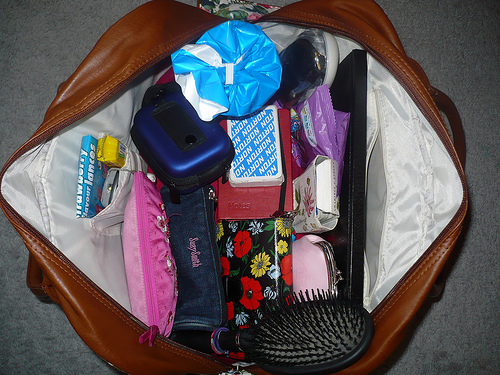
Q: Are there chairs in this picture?
A: No, there are no chairs.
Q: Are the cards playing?
A: Yes, the cards are playing.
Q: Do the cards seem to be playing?
A: Yes, the cards are playing.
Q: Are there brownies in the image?
A: No, there are no brownies.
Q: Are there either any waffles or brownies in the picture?
A: No, there are no brownies or waffles.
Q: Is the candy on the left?
A: Yes, the candy is on the left of the image.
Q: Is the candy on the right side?
A: No, the candy is on the left of the image.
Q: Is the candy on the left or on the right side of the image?
A: The candy is on the left of the image.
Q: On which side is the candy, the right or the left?
A: The candy is on the left of the image.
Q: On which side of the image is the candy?
A: The candy is on the left of the image.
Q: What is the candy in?
A: The candy is in the bag.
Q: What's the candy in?
A: The candy is in the bag.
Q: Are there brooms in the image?
A: No, there are no brooms.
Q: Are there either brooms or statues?
A: No, there are no brooms or statues.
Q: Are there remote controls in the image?
A: No, there are no remote controls.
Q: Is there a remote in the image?
A: No, there are no remote controls.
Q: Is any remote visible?
A: No, there are no remote controls.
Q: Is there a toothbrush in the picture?
A: No, there are no toothbrushes.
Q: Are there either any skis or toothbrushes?
A: No, there are no toothbrushes or skis.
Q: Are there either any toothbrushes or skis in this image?
A: No, there are no toothbrushes or skis.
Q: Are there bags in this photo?
A: Yes, there is a bag.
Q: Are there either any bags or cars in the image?
A: Yes, there is a bag.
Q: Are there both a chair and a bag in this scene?
A: No, there is a bag but no chairs.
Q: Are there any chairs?
A: No, there are no chairs.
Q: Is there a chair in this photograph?
A: No, there are no chairs.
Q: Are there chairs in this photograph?
A: No, there are no chairs.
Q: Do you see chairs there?
A: No, there are no chairs.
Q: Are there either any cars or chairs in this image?
A: No, there are no chairs or cars.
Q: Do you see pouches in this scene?
A: Yes, there is a pouch.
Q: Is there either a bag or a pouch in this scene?
A: Yes, there is a pouch.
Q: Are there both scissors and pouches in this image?
A: No, there is a pouch but no scissors.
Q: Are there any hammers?
A: No, there are no hammers.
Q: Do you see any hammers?
A: No, there are no hammers.